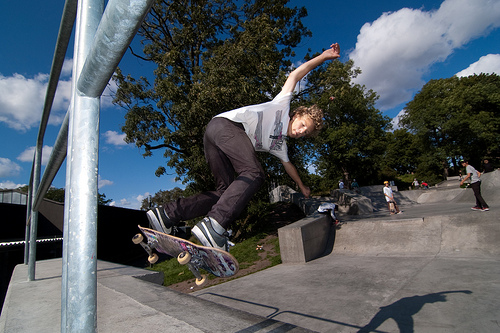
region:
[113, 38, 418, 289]
boy on a skateboard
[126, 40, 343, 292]
boy wearing a grey shirt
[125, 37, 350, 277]
boy wearing black jeans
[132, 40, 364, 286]
boy wearing tennis shoes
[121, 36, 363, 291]
boy with blonde hair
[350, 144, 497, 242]
spectators near the ramp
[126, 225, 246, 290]
skateboard with four wheels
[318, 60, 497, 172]
green forest trees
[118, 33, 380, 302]
boy leaning on skateboard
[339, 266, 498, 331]
shadow of boy on skateboard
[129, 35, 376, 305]
Completely in the air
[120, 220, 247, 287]
Lots of pictures under the board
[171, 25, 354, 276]
Arms out for balance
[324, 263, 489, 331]
Shadow of skateboarder on the ground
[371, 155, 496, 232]
People watching the skateboarder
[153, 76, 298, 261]
Wearing black pants and white shirt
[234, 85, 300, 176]
Gray stripes on shirt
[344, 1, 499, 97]
Brilliant blue sky with white puffy clouds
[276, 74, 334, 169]
Hair flying in the breeze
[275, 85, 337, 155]
Not wearing a helmet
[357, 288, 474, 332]
a shadow on the ground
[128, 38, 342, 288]
a boy on a skateboard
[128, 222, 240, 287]
a skateboard with torn up underside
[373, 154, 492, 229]
a couple kids at skateboard park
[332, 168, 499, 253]
an outdoor cement skateboard park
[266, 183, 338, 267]
a thick cement wall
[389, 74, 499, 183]
a large green tree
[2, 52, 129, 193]
a few cloud formations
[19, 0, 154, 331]
a metal fence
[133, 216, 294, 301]
a patch of grass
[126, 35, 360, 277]
boy doing a skateboarding trick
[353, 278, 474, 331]
shadow cast by a boy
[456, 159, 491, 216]
person wearing dark pants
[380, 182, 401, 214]
person wearing a white shirt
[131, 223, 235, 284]
colorful skateboard with white wheels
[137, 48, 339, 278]
boy wearing black pants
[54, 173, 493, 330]
cement skate park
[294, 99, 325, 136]
short blond curly hair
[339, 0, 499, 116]
big white fluffy cloud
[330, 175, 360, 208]
people sitting in the skate park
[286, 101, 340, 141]
Person has blonde hair.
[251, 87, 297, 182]
Person wearing white shirt.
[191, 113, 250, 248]
Person wearing black pants.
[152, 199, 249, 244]
Person wearing white socks.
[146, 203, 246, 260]
Person wearing white and black shoes.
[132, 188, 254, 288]
Person standing on skateboard.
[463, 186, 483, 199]
Person wearing black pants.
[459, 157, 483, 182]
Person wearing t-shirt.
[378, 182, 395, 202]
Person wearing white shirt.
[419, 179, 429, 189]
Person wearing red shirt.